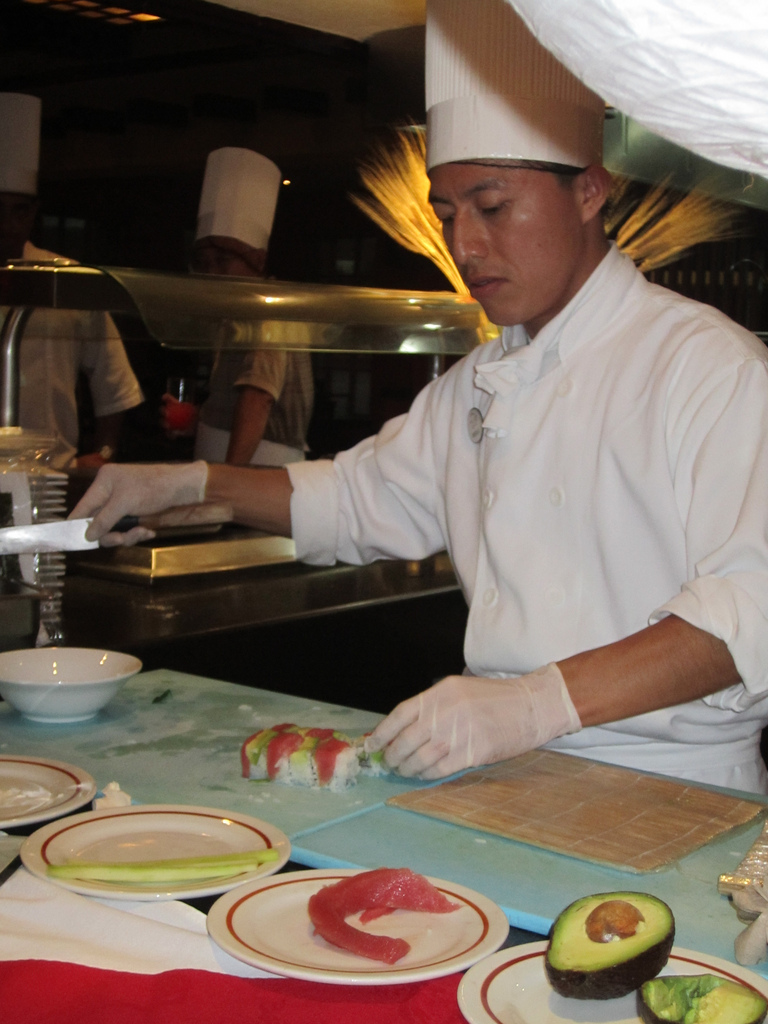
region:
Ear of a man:
[573, 161, 613, 225]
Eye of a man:
[475, 195, 507, 218]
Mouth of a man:
[462, 268, 509, 303]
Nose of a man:
[447, 210, 489, 265]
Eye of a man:
[427, 201, 455, 230]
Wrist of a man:
[537, 654, 591, 742]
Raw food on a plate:
[204, 854, 512, 988]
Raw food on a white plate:
[207, 859, 514, 995]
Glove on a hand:
[363, 653, 581, 786]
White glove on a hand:
[365, 648, 588, 787]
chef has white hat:
[375, 4, 556, 180]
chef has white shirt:
[366, 335, 766, 738]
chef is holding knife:
[2, 470, 150, 595]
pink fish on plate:
[194, 875, 479, 993]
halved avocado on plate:
[529, 869, 679, 998]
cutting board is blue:
[116, 650, 393, 903]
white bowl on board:
[10, 629, 143, 729]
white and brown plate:
[61, 788, 220, 903]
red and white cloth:
[40, 897, 313, 1020]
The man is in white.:
[503, 393, 654, 555]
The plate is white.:
[98, 787, 225, 868]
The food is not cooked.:
[302, 854, 452, 979]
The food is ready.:
[534, 890, 671, 1017]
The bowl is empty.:
[1, 632, 180, 745]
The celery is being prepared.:
[97, 819, 207, 902]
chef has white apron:
[287, 321, 720, 728]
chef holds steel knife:
[35, 464, 113, 546]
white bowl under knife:
[15, 633, 130, 742]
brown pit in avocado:
[577, 870, 657, 954]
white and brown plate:
[243, 864, 506, 971]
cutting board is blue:
[86, 655, 297, 822]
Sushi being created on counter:
[236, 711, 374, 799]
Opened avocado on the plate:
[539, 883, 680, 998]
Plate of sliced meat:
[310, 864, 463, 966]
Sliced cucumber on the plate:
[49, 851, 273, 882]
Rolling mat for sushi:
[368, 752, 766, 882]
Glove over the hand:
[361, 652, 585, 786]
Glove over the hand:
[57, 458, 211, 546]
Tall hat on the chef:
[192, 137, 283, 255]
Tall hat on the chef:
[421, 1, 611, 175]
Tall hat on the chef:
[4, 87, 44, 204]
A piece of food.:
[296, 865, 472, 964]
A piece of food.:
[540, 872, 693, 988]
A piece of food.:
[634, 970, 707, 1016]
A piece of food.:
[59, 850, 257, 888]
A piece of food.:
[269, 728, 301, 768]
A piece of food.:
[316, 737, 346, 786]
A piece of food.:
[336, 752, 363, 780]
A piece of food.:
[358, 749, 395, 774]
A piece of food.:
[303, 728, 342, 744]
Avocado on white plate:
[532, 883, 742, 1022]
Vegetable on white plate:
[539, 881, 754, 1021]